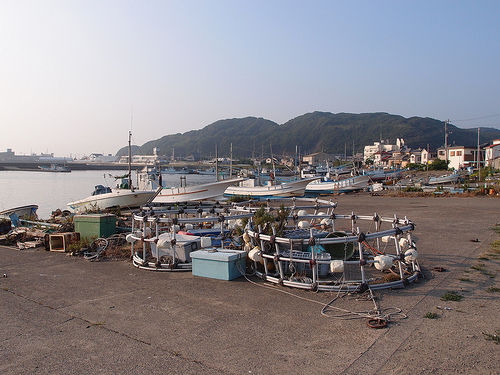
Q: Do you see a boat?
A: Yes, there is a boat.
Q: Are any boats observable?
A: Yes, there is a boat.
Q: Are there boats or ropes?
A: Yes, there is a boat.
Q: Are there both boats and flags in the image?
A: No, there is a boat but no flags.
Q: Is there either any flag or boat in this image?
A: Yes, there is a boat.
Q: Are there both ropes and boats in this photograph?
A: Yes, there are both a boat and a rope.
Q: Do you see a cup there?
A: No, there are no cups.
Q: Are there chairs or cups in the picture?
A: No, there are no cups or chairs.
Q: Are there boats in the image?
A: Yes, there is a boat.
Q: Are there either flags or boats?
A: Yes, there is a boat.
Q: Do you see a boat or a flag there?
A: Yes, there is a boat.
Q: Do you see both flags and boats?
A: No, there is a boat but no flags.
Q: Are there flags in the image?
A: No, there are no flags.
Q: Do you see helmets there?
A: No, there are no helmets.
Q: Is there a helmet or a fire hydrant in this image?
A: No, there are no helmets or fire hydrants.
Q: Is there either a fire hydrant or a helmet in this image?
A: No, there are no helmets or fire hydrants.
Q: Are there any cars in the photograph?
A: No, there are no cars.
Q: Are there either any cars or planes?
A: No, there are no cars or planes.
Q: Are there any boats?
A: Yes, there is a boat.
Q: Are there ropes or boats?
A: Yes, there is a boat.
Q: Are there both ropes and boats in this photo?
A: Yes, there are both a boat and a rope.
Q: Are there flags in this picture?
A: No, there are no flags.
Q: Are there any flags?
A: No, there are no flags.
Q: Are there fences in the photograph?
A: No, there are no fences.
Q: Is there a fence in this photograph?
A: No, there are no fences.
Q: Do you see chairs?
A: No, there are no chairs.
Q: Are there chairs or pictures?
A: No, there are no chairs or pictures.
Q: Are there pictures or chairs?
A: No, there are no chairs or pictures.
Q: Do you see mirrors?
A: No, there are no mirrors.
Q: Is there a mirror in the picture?
A: No, there are no mirrors.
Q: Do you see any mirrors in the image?
A: No, there are no mirrors.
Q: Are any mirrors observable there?
A: No, there are no mirrors.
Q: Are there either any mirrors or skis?
A: No, there are no mirrors or skis.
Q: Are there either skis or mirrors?
A: No, there are no mirrors or skis.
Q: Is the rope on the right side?
A: Yes, the rope is on the right of the image.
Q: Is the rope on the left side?
A: No, the rope is on the right of the image.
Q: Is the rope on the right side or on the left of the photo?
A: The rope is on the right of the image.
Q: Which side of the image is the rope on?
A: The rope is on the right of the image.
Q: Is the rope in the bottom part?
A: Yes, the rope is in the bottom of the image.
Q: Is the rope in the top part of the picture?
A: No, the rope is in the bottom of the image.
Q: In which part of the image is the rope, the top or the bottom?
A: The rope is in the bottom of the image.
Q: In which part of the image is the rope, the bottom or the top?
A: The rope is in the bottom of the image.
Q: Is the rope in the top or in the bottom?
A: The rope is in the bottom of the image.